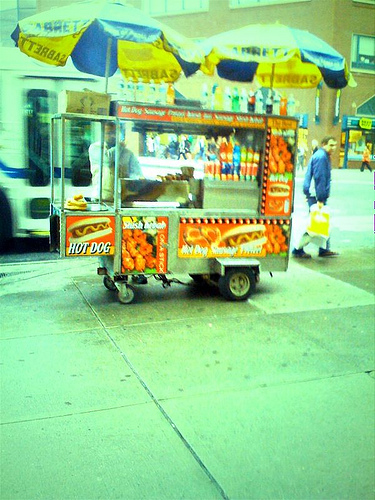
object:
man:
[88, 120, 151, 284]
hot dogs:
[63, 194, 88, 211]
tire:
[217, 267, 256, 302]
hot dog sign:
[67, 215, 115, 256]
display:
[49, 110, 263, 216]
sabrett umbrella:
[10, 1, 205, 86]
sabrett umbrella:
[198, 19, 357, 87]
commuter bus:
[0, 45, 170, 253]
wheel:
[116, 283, 137, 305]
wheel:
[103, 275, 117, 291]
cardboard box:
[57, 90, 111, 116]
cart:
[48, 99, 302, 304]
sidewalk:
[0, 245, 374, 499]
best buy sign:
[359, 117, 372, 129]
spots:
[195, 338, 272, 393]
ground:
[0, 316, 374, 499]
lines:
[2, 300, 375, 342]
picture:
[177, 223, 295, 258]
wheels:
[217, 267, 256, 302]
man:
[292, 134, 340, 261]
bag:
[305, 203, 330, 239]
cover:
[214, 258, 261, 278]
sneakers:
[317, 245, 340, 258]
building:
[35, 0, 375, 171]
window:
[348, 30, 375, 73]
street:
[0, 168, 374, 266]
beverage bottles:
[233, 142, 241, 162]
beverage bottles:
[265, 88, 275, 116]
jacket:
[302, 146, 332, 202]